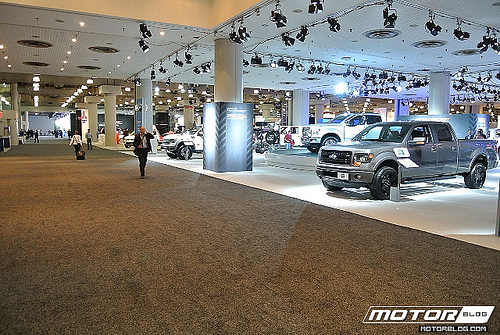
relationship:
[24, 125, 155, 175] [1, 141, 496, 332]
people are walking on carpet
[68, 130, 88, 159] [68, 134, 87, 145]
woman has shirt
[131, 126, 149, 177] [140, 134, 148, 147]
man has shirt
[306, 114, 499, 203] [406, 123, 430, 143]
truck has window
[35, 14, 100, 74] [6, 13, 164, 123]
lights in ceiling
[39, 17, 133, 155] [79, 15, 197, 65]
lights in room ceiling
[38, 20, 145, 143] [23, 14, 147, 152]
lights in ceiling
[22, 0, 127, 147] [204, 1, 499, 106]
lights in showroom ceiling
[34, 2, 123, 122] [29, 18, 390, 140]
lights in ceiling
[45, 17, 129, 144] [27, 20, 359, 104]
lights in ceiling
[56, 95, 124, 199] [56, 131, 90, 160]
woman pulling luggage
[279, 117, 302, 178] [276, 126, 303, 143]
person in shirt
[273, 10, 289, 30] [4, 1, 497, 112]
light on showroom ceiling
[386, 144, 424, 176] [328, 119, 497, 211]
label on truck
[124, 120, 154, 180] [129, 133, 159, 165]
man wearing suit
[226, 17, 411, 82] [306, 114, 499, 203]
lights above truck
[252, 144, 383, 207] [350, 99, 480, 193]
pedestal for white pickup truck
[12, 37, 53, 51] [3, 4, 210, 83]
air vent in ceiling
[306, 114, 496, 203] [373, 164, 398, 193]
truck has rim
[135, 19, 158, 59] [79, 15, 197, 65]
light on room ceiling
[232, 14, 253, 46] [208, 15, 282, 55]
light on ceiling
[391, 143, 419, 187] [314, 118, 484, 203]
display next to truck